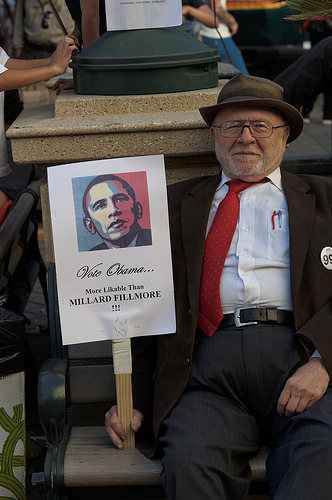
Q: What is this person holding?
A: A banner/poster.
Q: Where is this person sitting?
A: On a bench.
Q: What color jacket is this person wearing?
A: Brown.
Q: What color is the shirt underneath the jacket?
A: White.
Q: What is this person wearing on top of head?
A: A hat.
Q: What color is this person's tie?
A: Red.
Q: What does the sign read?
A: Vote Obama... More Likeable Than MILLARD FILLMORE.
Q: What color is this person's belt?
A: Black.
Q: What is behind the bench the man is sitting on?
A: A concrete pillar.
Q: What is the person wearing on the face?
A: Glasses.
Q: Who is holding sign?
A: Elderly man.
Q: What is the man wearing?
A: Suit and tie.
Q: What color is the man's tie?
A: Red.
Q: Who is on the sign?
A: President obama.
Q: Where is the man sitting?
A: Bench.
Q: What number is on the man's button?
A: 99.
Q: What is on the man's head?
A: A hat.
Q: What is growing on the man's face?
A: A bear.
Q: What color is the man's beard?
A: White.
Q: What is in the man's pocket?
A: Pens.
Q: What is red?
A: A tie.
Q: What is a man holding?
A: A sign.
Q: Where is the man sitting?
A: On a bench.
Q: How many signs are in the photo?
A: One.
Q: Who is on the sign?
A: Obama.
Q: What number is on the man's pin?
A: 99.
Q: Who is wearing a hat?
A: The man.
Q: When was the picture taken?
A: Daytime.